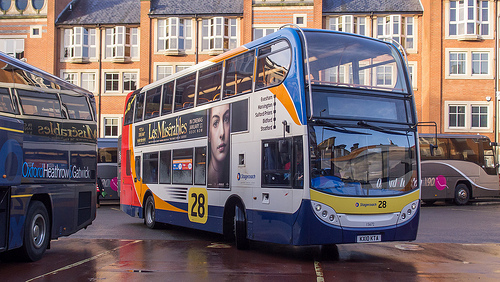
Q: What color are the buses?
A: Blue, white, gray, and yellow.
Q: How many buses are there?
A: Four.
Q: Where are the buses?
A: On the pavement.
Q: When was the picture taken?
A: Daytime.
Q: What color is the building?
A: Red.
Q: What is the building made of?
A: Bricks.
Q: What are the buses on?
A: Pavement.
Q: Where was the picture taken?
A: On the street.